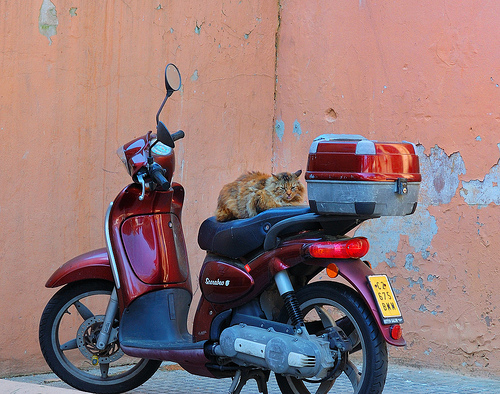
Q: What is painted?
A: A wall.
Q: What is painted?
A: A wall.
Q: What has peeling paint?
A: A building.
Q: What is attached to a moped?
A: A case.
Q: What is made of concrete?
A: Walls.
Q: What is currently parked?
A: A moped.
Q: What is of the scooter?
A: Back wheel.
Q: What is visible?
A: A scooter.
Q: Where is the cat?
A: On the scooter.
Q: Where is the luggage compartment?
A: Behind the seat on the scooter.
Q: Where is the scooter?
A: Parked near a wall.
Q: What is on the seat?
A: The cat.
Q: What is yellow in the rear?
A: The license plate.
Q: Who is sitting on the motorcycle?
A: A cat.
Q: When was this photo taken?
A: During the daytime.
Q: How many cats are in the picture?
A: One.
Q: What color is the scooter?
A: Red.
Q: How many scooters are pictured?
A: One.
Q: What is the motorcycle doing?
A: Parked.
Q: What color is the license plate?
A: Yellow.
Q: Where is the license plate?
A: On rear fender.